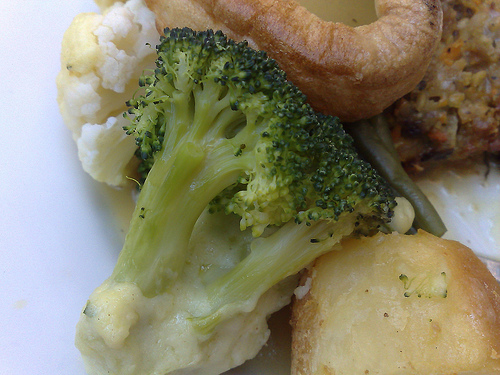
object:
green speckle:
[315, 167, 328, 178]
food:
[143, 0, 443, 123]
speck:
[63, 61, 75, 74]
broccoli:
[73, 28, 398, 374]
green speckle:
[269, 90, 288, 99]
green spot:
[137, 207, 145, 220]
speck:
[397, 269, 413, 291]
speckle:
[203, 206, 218, 216]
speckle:
[331, 137, 343, 145]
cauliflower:
[56, 0, 164, 186]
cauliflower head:
[121, 25, 401, 240]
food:
[290, 228, 500, 375]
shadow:
[76, 163, 139, 260]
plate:
[0, 1, 299, 373]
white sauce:
[76, 278, 288, 373]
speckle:
[322, 179, 335, 193]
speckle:
[352, 172, 364, 184]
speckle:
[288, 160, 306, 174]